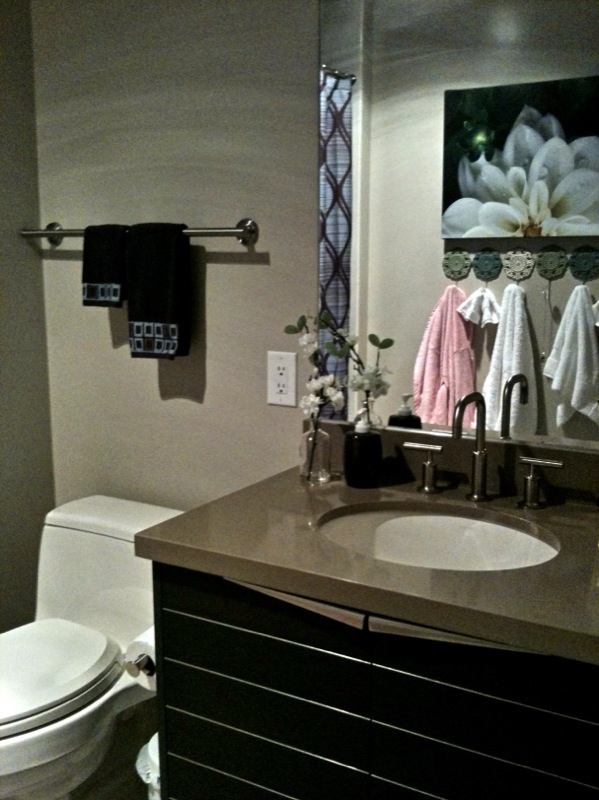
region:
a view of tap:
[366, 286, 528, 492]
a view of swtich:
[237, 304, 307, 422]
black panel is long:
[155, 562, 368, 660]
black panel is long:
[163, 609, 368, 714]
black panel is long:
[164, 659, 368, 771]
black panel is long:
[166, 704, 373, 797]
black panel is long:
[164, 751, 295, 798]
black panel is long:
[375, 772, 440, 798]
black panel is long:
[368, 614, 597, 720]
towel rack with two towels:
[12, 193, 274, 374]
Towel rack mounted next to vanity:
[7, 192, 273, 370]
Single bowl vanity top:
[123, 400, 584, 651]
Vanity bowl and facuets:
[296, 348, 590, 641]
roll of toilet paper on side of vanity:
[115, 602, 158, 698]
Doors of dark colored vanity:
[149, 555, 584, 796]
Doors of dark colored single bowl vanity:
[137, 535, 590, 789]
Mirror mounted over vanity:
[307, 189, 595, 460]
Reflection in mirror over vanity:
[362, 208, 593, 432]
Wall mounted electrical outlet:
[247, 333, 306, 430]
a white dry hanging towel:
[539, 279, 597, 424]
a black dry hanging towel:
[77, 223, 128, 306]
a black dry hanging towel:
[124, 219, 195, 355]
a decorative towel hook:
[438, 247, 470, 287]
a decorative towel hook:
[470, 247, 499, 292]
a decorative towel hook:
[498, 245, 536, 291]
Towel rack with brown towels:
[15, 207, 259, 365]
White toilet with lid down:
[2, 485, 188, 796]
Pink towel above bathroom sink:
[407, 276, 481, 430]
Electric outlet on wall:
[261, 345, 299, 411]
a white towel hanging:
[553, 291, 595, 380]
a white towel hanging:
[472, 269, 535, 393]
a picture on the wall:
[382, 77, 546, 295]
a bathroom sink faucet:
[465, 391, 488, 496]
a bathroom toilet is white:
[70, 470, 147, 612]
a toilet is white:
[39, 485, 133, 668]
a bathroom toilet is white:
[56, 525, 107, 713]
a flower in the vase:
[317, 330, 383, 444]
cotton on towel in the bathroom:
[122, 214, 191, 357]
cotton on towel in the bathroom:
[76, 218, 125, 307]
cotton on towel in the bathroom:
[409, 285, 474, 433]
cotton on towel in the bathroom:
[455, 280, 496, 329]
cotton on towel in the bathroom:
[476, 285, 540, 438]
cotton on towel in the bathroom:
[523, 272, 595, 427]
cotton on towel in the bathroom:
[123, 221, 193, 359]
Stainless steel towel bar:
[20, 216, 257, 245]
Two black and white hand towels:
[80, 223, 190, 359]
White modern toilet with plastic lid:
[1, 493, 181, 798]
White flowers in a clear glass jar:
[299, 374, 345, 479]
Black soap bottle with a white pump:
[343, 406, 382, 487]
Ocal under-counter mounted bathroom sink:
[314, 499, 560, 575]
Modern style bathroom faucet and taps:
[403, 390, 563, 510]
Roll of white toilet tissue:
[123, 622, 155, 692]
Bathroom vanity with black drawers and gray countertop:
[134, 466, 596, 798]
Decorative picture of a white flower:
[441, 75, 597, 240]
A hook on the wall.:
[435, 247, 469, 291]